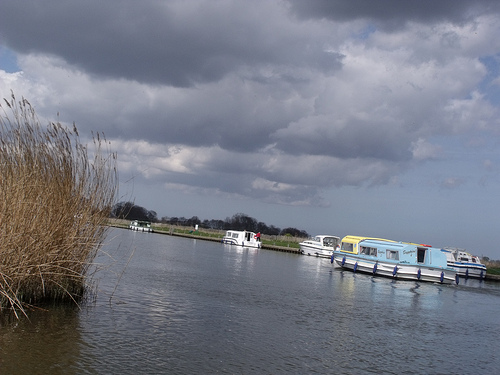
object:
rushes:
[1, 92, 118, 323]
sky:
[21, 18, 486, 243]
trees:
[113, 201, 157, 222]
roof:
[340, 235, 432, 254]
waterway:
[0, 220, 499, 374]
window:
[386, 250, 399, 260]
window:
[360, 246, 377, 257]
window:
[341, 242, 352, 252]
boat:
[436, 247, 487, 278]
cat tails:
[0, 90, 120, 319]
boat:
[223, 230, 262, 249]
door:
[418, 248, 426, 263]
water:
[1, 247, 498, 374]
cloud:
[2, 1, 500, 208]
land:
[139, 220, 298, 251]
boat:
[299, 235, 341, 258]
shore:
[97, 221, 300, 252]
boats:
[130, 220, 153, 232]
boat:
[332, 235, 458, 284]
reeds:
[1, 92, 121, 321]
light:
[147, 287, 167, 329]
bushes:
[0, 91, 121, 319]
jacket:
[256, 233, 261, 238]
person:
[256, 232, 261, 242]